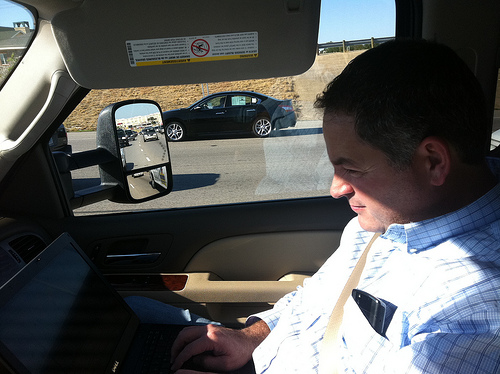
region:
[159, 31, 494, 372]
a man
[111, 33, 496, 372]
a man in a car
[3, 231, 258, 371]
a laptop computer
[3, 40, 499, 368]
a laptop computer is on the man's lap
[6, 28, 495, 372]
the man is using a laptop computer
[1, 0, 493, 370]
the man is in a car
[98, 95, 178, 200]
other cars are reflected in the side mirror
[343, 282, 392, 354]
the man has a cellphone in his shirt pocket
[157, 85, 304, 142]
a car with papers in the window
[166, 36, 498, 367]
the man is wearing a checkered shirt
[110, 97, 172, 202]
the side view mirror on the car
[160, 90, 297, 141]
the car on the street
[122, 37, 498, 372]
the man sitting in the car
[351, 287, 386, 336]
the object in the man's pocket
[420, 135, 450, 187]
the ear on the man's head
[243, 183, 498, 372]
the long sleeved shirt on the man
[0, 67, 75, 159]
the handle in the car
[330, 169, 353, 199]
the nose on the man's face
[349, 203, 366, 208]
the mouth on the man's face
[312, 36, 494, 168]
the hair on the man's head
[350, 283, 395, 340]
black cell phone in front pocket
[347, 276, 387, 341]
cell phone in pocket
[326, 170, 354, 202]
nose of a man in sunlight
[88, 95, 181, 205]
side mirror of truck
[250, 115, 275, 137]
rear wheel of a car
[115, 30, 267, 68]
airbag warning symbol on sun visor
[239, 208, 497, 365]
white and blue plaid shirt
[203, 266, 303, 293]
handle to pull door closed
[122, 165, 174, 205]
spot mirror on bottom of main mirror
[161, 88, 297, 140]
Black car parked at the curb.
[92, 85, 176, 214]
Large side mirror on the car.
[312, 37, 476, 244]
Man squinting because of the sun.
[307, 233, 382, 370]
Man wearing a seat belt for safety.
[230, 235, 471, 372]
Sun shining on the man.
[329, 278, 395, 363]
Cell phone in a pocket.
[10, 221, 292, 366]
Working on a lap top in the car.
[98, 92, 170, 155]
Cars in the distance.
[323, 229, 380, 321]
tan fabric neck tie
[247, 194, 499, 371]
white button down shirt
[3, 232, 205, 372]
black laptop on mans lap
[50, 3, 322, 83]
tan visor on car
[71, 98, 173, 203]
side mirror on car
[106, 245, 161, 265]
silver handle on car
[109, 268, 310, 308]
arm rest on car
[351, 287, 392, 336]
cell phone in pocket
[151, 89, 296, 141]
black car on street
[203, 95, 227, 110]
glass window on car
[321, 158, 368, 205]
nose of the person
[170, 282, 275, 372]
hand of the man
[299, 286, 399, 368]
pocket on the shirt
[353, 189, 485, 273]
collar on the shirt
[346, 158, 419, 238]
shadow on the face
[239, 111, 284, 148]
back tire of car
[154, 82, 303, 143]
black car driving next to driver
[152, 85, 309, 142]
black car driving next to driver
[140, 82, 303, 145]
black car driving next to driver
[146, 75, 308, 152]
black car driving next to driver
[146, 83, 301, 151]
black car driving next to driver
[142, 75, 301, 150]
black car driving next to driver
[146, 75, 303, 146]
black car driving next to driver